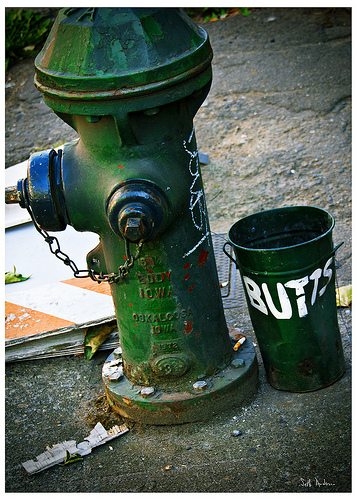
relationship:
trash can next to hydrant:
[222, 206, 347, 392] [4, 8, 259, 426]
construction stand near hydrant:
[6, 160, 140, 359] [4, 8, 259, 426]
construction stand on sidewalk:
[6, 160, 140, 359] [5, 6, 352, 493]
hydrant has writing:
[4, 8, 259, 426] [130, 271, 195, 350]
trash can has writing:
[222, 206, 347, 392] [241, 258, 333, 320]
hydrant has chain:
[4, 8, 259, 426] [25, 200, 142, 282]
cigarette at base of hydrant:
[234, 334, 245, 350] [4, 8, 259, 426]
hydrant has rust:
[4, 8, 259, 426] [182, 247, 210, 340]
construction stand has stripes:
[6, 160, 140, 359] [4, 275, 114, 344]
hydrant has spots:
[4, 8, 259, 426] [182, 247, 210, 340]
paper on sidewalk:
[20, 421, 128, 474] [5, 6, 352, 493]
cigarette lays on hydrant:
[234, 334, 245, 350] [4, 8, 259, 426]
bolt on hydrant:
[119, 207, 153, 241] [4, 8, 259, 426]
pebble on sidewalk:
[233, 430, 241, 435] [5, 6, 352, 493]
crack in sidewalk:
[226, 38, 349, 56] [5, 6, 352, 493]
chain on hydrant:
[25, 200, 142, 282] [4, 8, 259, 426]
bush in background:
[7, 9, 234, 79] [8, 8, 350, 97]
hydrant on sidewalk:
[4, 8, 259, 426] [6, 8, 353, 492]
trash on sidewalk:
[20, 421, 128, 474] [5, 6, 352, 493]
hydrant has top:
[4, 8, 259, 426] [32, 8, 212, 96]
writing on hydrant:
[130, 271, 195, 350] [4, 8, 259, 426]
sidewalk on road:
[5, 6, 352, 493] [6, 8, 353, 492]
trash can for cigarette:
[222, 204, 346, 391] [234, 334, 245, 350]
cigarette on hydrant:
[234, 334, 245, 350] [4, 8, 259, 426]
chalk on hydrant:
[176, 126, 211, 258] [4, 8, 259, 426]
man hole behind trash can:
[200, 234, 245, 305] [222, 204, 346, 391]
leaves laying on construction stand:
[6, 265, 31, 286] [6, 160, 140, 359]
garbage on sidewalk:
[20, 421, 128, 474] [6, 8, 353, 492]